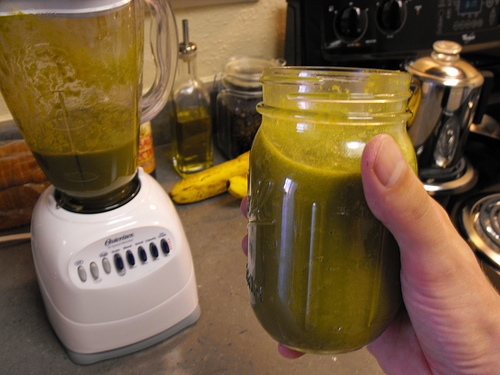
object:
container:
[213, 53, 287, 161]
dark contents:
[218, 97, 251, 139]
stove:
[281, 0, 500, 69]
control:
[330, 3, 372, 44]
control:
[373, 2, 412, 35]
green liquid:
[32, 135, 142, 199]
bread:
[0, 140, 48, 229]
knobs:
[321, 0, 355, 26]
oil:
[179, 107, 216, 171]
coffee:
[378, 38, 489, 182]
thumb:
[360, 132, 462, 277]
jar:
[247, 62, 422, 356]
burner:
[456, 185, 498, 289]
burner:
[410, 162, 481, 204]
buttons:
[74, 265, 87, 281]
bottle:
[170, 16, 216, 180]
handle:
[138, 1, 182, 125]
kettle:
[404, 39, 486, 223]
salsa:
[248, 127, 417, 351]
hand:
[238, 132, 498, 374]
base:
[29, 162, 200, 364]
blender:
[0, 0, 203, 362]